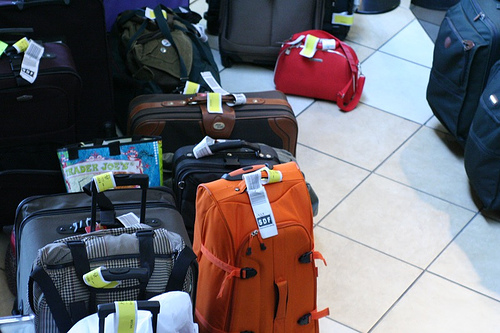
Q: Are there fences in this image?
A: No, there are no fences.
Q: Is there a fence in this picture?
A: No, there are no fences.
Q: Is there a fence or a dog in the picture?
A: No, there are no fences or dogs.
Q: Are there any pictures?
A: No, there are no pictures.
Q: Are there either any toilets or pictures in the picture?
A: No, there are no pictures or toilets.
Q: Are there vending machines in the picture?
A: No, there are no vending machines.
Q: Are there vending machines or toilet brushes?
A: No, there are no vending machines or toilet brushes.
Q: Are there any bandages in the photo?
A: No, there are no bandages.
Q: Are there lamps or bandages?
A: No, there are no bandages or lamps.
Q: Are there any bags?
A: Yes, there is a bag.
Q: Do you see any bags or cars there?
A: Yes, there is a bag.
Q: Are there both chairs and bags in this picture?
A: No, there is a bag but no chairs.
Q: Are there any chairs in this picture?
A: No, there are no chairs.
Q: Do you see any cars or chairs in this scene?
A: No, there are no chairs or cars.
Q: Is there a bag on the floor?
A: Yes, there is a bag on the floor.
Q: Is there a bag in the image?
A: Yes, there is a bag.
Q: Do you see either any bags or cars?
A: Yes, there is a bag.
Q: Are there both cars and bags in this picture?
A: No, there is a bag but no cars.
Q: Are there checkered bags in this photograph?
A: Yes, there is a checkered bag.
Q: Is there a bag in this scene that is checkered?
A: Yes, there is a bag that is checkered.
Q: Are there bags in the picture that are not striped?
A: Yes, there is a checkered bag.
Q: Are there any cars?
A: No, there are no cars.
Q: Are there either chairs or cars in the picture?
A: No, there are no cars or chairs.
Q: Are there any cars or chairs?
A: No, there are no cars or chairs.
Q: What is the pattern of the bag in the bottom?
A: The bag is checkered.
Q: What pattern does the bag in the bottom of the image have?
A: The bag has checkered pattern.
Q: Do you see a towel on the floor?
A: No, there is a bag on the floor.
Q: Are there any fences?
A: No, there are no fences.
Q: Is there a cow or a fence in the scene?
A: No, there are no fences or cows.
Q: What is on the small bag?
A: The tag is on the bag.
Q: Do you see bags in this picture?
A: Yes, there is a bag.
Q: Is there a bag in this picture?
A: Yes, there is a bag.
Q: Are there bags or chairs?
A: Yes, there is a bag.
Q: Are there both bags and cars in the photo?
A: No, there is a bag but no cars.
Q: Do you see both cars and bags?
A: No, there is a bag but no cars.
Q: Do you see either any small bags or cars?
A: Yes, there is a small bag.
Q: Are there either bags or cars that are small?
A: Yes, the bag is small.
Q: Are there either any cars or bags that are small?
A: Yes, the bag is small.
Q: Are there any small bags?
A: Yes, there is a small bag.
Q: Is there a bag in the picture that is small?
A: Yes, there is a bag that is small.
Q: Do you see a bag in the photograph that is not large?
A: Yes, there is a small bag.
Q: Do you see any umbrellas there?
A: No, there are no umbrellas.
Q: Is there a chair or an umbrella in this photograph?
A: No, there are no umbrellas or chairs.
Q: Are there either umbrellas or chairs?
A: No, there are no umbrellas or chairs.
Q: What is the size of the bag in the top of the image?
A: The bag is small.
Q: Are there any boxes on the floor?
A: No, there is a bag on the floor.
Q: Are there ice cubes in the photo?
A: No, there are no ice cubes.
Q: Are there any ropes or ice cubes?
A: No, there are no ice cubes or ropes.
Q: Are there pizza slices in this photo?
A: No, there are no pizza slices.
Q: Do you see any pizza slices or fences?
A: No, there are no pizza slices or fences.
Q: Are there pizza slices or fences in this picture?
A: No, there are no pizza slices or fences.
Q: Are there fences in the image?
A: No, there are no fences.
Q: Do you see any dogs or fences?
A: No, there are no fences or dogs.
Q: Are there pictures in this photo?
A: No, there are no pictures.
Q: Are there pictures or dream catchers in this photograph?
A: No, there are no pictures or dream catchers.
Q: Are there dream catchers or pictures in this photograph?
A: No, there are no pictures or dream catchers.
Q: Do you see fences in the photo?
A: No, there are no fences.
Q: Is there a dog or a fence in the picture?
A: No, there are no fences or dogs.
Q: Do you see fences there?
A: No, there are no fences.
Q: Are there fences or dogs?
A: No, there are no fences or dogs.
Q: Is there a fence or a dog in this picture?
A: No, there are no fences or dogs.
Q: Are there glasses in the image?
A: No, there are no glasses.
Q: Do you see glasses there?
A: No, there are no glasses.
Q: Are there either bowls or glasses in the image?
A: No, there are no glasses or bowls.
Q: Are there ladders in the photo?
A: No, there are no ladders.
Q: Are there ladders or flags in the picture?
A: No, there are no ladders or flags.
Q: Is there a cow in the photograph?
A: No, there are no cows.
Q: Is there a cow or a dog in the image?
A: No, there are no cows or dogs.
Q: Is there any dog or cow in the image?
A: No, there are no cows or dogs.